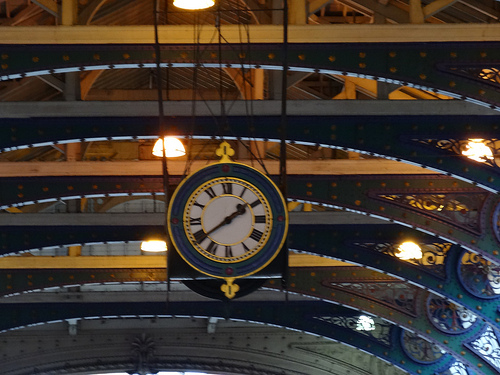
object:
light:
[170, 0, 213, 11]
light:
[354, 314, 377, 336]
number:
[250, 199, 263, 210]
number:
[225, 246, 233, 257]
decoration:
[215, 141, 235, 162]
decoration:
[220, 278, 241, 298]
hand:
[195, 221, 225, 245]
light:
[394, 237, 424, 262]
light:
[461, 135, 495, 162]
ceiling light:
[140, 240, 169, 253]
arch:
[0, 58, 500, 123]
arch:
[0, 184, 401, 235]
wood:
[222, 67, 270, 99]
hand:
[228, 202, 249, 220]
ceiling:
[3, 78, 371, 102]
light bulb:
[162, 143, 176, 150]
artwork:
[125, 332, 159, 374]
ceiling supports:
[332, 81, 357, 100]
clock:
[165, 162, 289, 279]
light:
[152, 135, 186, 159]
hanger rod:
[152, 2, 170, 198]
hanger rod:
[278, 0, 289, 190]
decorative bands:
[168, 91, 239, 100]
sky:
[1, 62, 498, 112]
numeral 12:
[221, 183, 233, 194]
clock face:
[182, 177, 275, 264]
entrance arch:
[0, 315, 412, 373]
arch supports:
[1, 314, 448, 375]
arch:
[0, 121, 500, 194]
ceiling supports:
[67, 246, 82, 257]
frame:
[146, 0, 294, 164]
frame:
[324, 116, 447, 155]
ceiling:
[0, 0, 477, 24]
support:
[0, 314, 412, 375]